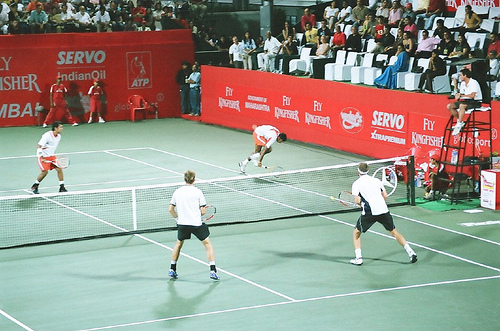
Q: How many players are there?
A: Four.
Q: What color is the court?
A: Green.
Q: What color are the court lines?
A: White.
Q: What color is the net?
A: Black and white.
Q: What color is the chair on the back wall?
A: Red.